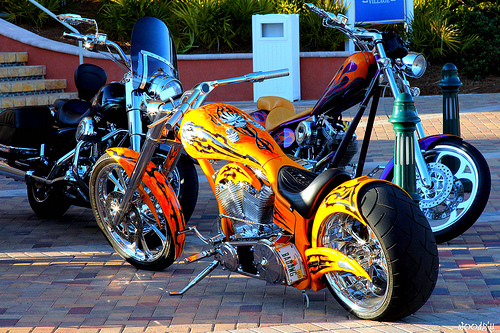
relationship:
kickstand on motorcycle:
[157, 257, 226, 304] [93, 66, 440, 329]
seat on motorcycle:
[275, 154, 340, 224] [88, 55, 426, 318]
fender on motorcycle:
[310, 172, 380, 246] [93, 66, 440, 329]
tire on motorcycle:
[324, 181, 436, 326] [88, 55, 426, 318]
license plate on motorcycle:
[277, 246, 313, 296] [93, 66, 440, 329]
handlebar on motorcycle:
[192, 68, 295, 93] [93, 66, 440, 329]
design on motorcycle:
[210, 108, 273, 162] [93, 66, 440, 329]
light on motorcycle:
[142, 74, 185, 112] [64, 30, 436, 328]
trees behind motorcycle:
[4, 3, 496, 106] [93, 66, 440, 329]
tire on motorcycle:
[302, 181, 443, 321] [88, 55, 426, 318]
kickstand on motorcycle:
[146, 252, 216, 304] [64, 30, 436, 328]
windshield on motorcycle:
[121, 46, 181, 98] [64, 30, 436, 328]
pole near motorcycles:
[432, 70, 470, 135] [8, 6, 495, 320]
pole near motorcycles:
[384, 90, 429, 199] [8, 6, 495, 320]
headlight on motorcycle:
[399, 55, 426, 82] [253, 6, 498, 253]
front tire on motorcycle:
[84, 148, 187, 275] [64, 30, 436, 328]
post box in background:
[251, 54, 273, 89] [65, 109, 464, 258]